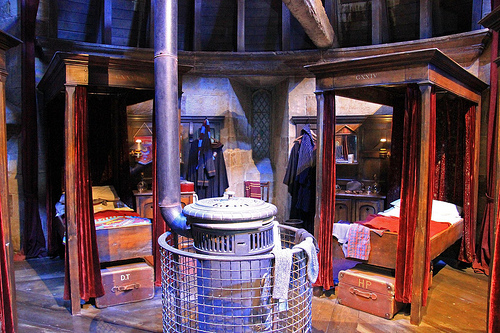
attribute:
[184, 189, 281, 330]
gas heater — wood burning, small, for heating, metal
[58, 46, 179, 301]
canopy post bed — wooden, large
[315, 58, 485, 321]
canopy post bed — wooden, large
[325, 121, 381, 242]
vanity station — wooden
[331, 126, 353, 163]
mirror — small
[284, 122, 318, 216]
coat rack — dark wood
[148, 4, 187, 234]
heat pipe — metal, long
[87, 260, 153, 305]
bed drawer — personalized, wooden, etched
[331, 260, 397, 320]
bed drawer — personalized, wooden, etched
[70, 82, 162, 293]
curtain — red, velvet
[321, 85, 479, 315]
curtain — red, velvet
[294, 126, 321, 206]
bathrobe — blue, black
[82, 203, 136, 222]
blanket — red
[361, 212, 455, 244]
blanket — red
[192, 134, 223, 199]
robe — black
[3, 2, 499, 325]
bedroom — loft style, harry potter theme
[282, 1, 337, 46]
beam — wooden, large, exposed, wood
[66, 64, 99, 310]
column — wooden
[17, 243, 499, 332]
floor — wooden, light wood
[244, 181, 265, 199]
scarf — gold, red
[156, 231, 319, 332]
basket — metal